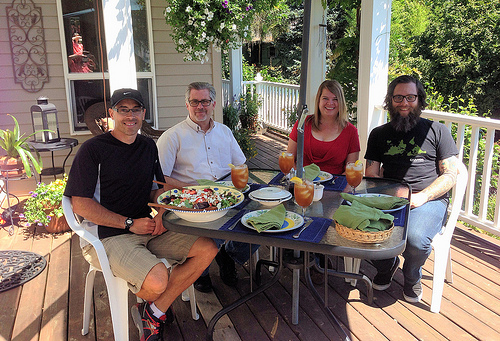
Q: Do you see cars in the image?
A: No, there are no cars.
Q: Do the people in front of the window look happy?
A: Yes, the people are happy.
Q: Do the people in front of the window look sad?
A: No, the people are happy.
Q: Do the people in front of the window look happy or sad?
A: The people are happy.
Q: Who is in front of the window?
A: The people are in front of the window.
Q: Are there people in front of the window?
A: Yes, there are people in front of the window.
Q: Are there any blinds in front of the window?
A: No, there are people in front of the window.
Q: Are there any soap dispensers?
A: No, there are no soap dispensers.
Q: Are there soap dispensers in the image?
A: No, there are no soap dispensers.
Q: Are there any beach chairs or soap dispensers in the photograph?
A: No, there are no soap dispensers or beach chairs.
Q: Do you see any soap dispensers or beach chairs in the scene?
A: No, there are no soap dispensers or beach chairs.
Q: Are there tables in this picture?
A: Yes, there is a table.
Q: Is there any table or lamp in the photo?
A: Yes, there is a table.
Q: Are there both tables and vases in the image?
A: No, there is a table but no vases.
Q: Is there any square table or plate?
A: Yes, there is a square table.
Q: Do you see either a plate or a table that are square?
A: Yes, the table is square.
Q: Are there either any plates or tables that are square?
A: Yes, the table is square.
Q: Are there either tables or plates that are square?
A: Yes, the table is square.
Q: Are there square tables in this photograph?
A: Yes, there is a square table.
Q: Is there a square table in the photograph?
A: Yes, there is a square table.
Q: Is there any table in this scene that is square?
A: Yes, there is a table that is square.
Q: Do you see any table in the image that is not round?
A: Yes, there is a square table.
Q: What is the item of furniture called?
A: The piece of furniture is a table.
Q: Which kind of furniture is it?
A: The piece of furniture is a table.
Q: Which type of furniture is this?
A: That is a table.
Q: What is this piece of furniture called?
A: That is a table.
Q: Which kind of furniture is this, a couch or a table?
A: That is a table.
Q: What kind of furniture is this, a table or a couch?
A: That is a table.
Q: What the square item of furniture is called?
A: The piece of furniture is a table.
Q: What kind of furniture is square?
A: The furniture is a table.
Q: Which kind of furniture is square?
A: The furniture is a table.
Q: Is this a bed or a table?
A: This is a table.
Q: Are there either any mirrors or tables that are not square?
A: No, there is a table but it is square.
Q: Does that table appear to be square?
A: Yes, the table is square.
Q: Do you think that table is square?
A: Yes, the table is square.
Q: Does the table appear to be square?
A: Yes, the table is square.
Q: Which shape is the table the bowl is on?
A: The table is square.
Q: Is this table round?
A: No, the table is square.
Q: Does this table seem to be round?
A: No, the table is square.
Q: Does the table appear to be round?
A: No, the table is square.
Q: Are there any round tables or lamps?
A: No, there is a table but it is square.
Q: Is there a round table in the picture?
A: No, there is a table but it is square.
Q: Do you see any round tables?
A: No, there is a table but it is square.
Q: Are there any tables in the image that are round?
A: No, there is a table but it is square.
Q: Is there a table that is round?
A: No, there is a table but it is square.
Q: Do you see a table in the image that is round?
A: No, there is a table but it is square.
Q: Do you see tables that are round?
A: No, there is a table but it is square.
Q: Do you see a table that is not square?
A: No, there is a table but it is square.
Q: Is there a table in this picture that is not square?
A: No, there is a table but it is square.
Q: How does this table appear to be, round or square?
A: The table is square.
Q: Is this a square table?
A: Yes, this is a square table.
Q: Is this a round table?
A: No, this is a square table.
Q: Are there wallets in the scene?
A: No, there are no wallets.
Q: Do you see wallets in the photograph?
A: No, there are no wallets.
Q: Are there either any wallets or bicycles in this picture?
A: No, there are no wallets or bicycles.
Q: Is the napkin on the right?
A: Yes, the napkin is on the right of the image.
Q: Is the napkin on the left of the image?
A: No, the napkin is on the right of the image.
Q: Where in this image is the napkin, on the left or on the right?
A: The napkin is on the right of the image.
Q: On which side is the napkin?
A: The napkin is on the right of the image.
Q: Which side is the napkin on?
A: The napkin is on the right of the image.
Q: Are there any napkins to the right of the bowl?
A: Yes, there is a napkin to the right of the bowl.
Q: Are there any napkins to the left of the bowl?
A: No, the napkin is to the right of the bowl.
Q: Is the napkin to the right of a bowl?
A: Yes, the napkin is to the right of a bowl.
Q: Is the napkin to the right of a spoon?
A: No, the napkin is to the right of a bowl.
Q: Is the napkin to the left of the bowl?
A: No, the napkin is to the right of the bowl.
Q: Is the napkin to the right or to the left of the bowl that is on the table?
A: The napkin is to the right of the bowl.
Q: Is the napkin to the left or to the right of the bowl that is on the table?
A: The napkin is to the right of the bowl.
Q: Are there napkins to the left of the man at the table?
A: Yes, there is a napkin to the left of the man.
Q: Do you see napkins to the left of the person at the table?
A: Yes, there is a napkin to the left of the man.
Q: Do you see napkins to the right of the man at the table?
A: No, the napkin is to the left of the man.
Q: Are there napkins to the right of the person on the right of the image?
A: No, the napkin is to the left of the man.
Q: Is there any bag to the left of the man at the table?
A: No, there is a napkin to the left of the man.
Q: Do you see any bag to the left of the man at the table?
A: No, there is a napkin to the left of the man.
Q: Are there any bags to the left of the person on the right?
A: No, there is a napkin to the left of the man.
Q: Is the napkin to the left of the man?
A: Yes, the napkin is to the left of the man.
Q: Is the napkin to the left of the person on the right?
A: Yes, the napkin is to the left of the man.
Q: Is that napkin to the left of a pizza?
A: No, the napkin is to the left of the man.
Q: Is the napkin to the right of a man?
A: No, the napkin is to the left of a man.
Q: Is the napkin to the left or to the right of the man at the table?
A: The napkin is to the left of the man.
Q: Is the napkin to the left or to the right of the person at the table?
A: The napkin is to the left of the man.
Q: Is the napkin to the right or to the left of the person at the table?
A: The napkin is to the left of the man.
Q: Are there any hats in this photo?
A: Yes, there is a hat.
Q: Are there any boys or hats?
A: Yes, there is a hat.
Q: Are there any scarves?
A: No, there are no scarves.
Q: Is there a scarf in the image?
A: No, there are no scarves.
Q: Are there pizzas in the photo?
A: No, there are no pizzas.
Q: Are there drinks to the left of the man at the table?
A: Yes, there is a drink to the left of the man.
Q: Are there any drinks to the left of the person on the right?
A: Yes, there is a drink to the left of the man.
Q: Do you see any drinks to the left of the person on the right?
A: Yes, there is a drink to the left of the man.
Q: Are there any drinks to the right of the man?
A: No, the drink is to the left of the man.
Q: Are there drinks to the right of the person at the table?
A: No, the drink is to the left of the man.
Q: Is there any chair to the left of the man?
A: No, there is a drink to the left of the man.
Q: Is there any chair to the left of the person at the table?
A: No, there is a drink to the left of the man.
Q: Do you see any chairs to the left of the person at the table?
A: No, there is a drink to the left of the man.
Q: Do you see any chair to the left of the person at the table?
A: No, there is a drink to the left of the man.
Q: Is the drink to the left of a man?
A: Yes, the drink is to the left of a man.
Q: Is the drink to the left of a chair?
A: No, the drink is to the left of a man.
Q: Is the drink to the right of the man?
A: No, the drink is to the left of the man.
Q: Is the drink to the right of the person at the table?
A: No, the drink is to the left of the man.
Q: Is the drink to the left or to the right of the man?
A: The drink is to the left of the man.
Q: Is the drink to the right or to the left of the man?
A: The drink is to the left of the man.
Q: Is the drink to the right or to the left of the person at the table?
A: The drink is to the left of the man.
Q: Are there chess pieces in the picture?
A: No, there are no chess pieces.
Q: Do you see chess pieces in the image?
A: No, there are no chess pieces.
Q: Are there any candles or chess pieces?
A: No, there are no chess pieces or candles.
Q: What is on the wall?
A: The artwork is on the wall.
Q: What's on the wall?
A: The artwork is on the wall.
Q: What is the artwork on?
A: The artwork is on the wall.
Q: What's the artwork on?
A: The artwork is on the wall.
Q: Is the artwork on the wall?
A: Yes, the artwork is on the wall.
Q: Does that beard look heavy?
A: Yes, the beard is heavy.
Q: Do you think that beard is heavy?
A: Yes, the beard is heavy.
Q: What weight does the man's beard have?
A: The beard has heavy weight.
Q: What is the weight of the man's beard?
A: The beard is heavy.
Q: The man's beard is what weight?
A: The beard is heavy.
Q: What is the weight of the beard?
A: The beard is heavy.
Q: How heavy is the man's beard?
A: The beard is heavy.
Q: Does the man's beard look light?
A: No, the beard is heavy.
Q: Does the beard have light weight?
A: No, the beard is heavy.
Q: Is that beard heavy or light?
A: The beard is heavy.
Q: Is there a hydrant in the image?
A: No, there are no fire hydrants.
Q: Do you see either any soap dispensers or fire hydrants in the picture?
A: No, there are no fire hydrants or soap dispensers.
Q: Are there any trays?
A: No, there are no trays.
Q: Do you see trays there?
A: No, there are no trays.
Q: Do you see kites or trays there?
A: No, there are no trays or kites.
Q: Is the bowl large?
A: Yes, the bowl is large.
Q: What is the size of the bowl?
A: The bowl is large.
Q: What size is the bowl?
A: The bowl is large.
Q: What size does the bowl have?
A: The bowl has large size.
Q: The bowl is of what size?
A: The bowl is large.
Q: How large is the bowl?
A: The bowl is large.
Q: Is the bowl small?
A: No, the bowl is large.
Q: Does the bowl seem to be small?
A: No, the bowl is large.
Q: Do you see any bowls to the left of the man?
A: Yes, there is a bowl to the left of the man.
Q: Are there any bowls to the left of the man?
A: Yes, there is a bowl to the left of the man.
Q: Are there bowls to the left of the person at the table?
A: Yes, there is a bowl to the left of the man.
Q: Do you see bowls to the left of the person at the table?
A: Yes, there is a bowl to the left of the man.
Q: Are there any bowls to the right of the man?
A: No, the bowl is to the left of the man.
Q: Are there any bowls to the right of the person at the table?
A: No, the bowl is to the left of the man.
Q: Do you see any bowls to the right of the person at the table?
A: No, the bowl is to the left of the man.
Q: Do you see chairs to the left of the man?
A: No, there is a bowl to the left of the man.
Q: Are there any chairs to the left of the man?
A: No, there is a bowl to the left of the man.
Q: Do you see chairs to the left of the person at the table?
A: No, there is a bowl to the left of the man.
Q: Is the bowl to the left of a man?
A: Yes, the bowl is to the left of a man.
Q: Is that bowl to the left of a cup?
A: No, the bowl is to the left of a man.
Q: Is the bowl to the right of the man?
A: No, the bowl is to the left of the man.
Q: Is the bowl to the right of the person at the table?
A: No, the bowl is to the left of the man.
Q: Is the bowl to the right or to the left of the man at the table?
A: The bowl is to the left of the man.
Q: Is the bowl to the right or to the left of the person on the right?
A: The bowl is to the left of the man.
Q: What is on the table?
A: The bowl is on the table.